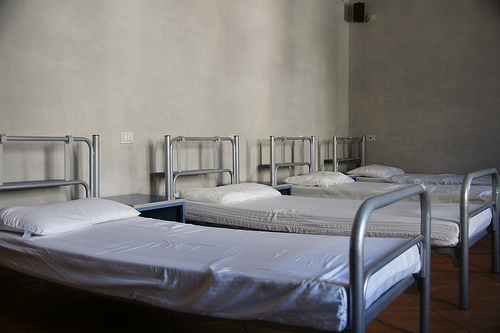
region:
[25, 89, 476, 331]
a row of beds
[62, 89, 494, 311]
beds in a row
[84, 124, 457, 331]
beds without blankets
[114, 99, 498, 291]
mattress covered in plastic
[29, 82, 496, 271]
tables in between beds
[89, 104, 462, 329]
a row of beds and table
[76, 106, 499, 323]
beds against the wall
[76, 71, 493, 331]
a row of beds inside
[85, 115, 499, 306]
beds that are inside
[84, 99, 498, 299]
beds with plastic mattress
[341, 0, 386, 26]
A piece of equipment attached to the wall.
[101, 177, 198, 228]
A table between the beds.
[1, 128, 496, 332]
Four gray iron beds.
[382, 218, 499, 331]
Brown concrete flooring.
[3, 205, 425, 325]
Four unmade beds with white coverlets.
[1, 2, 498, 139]
Gray concrete walls.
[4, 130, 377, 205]
The beds made shadows on the wall.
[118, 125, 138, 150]
The bed numbers are on the wall.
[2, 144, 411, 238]
A pillow is on each bed.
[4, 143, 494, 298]
The beds are empty.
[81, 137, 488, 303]
Four beds in the room.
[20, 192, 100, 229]
A pillow on the bed.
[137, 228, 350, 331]
The sheets are white.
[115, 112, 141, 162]
A light switch on the wall.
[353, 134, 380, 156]
An outlet on the wall.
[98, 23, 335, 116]
The wall is white.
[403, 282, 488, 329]
The floor is brown.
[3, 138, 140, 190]
The headboard is iron.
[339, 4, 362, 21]
A speaker in the corner.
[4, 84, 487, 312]
Four unoccupied beds with no sheets.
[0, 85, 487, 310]
Four unoccupied beds with no sheets in a room.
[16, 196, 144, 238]
pillow on a bed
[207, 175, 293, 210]
pillow on a bed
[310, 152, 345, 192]
pillow on a bed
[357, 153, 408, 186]
pillow on a bed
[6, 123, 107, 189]
head board of a bed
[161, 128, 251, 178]
head board on a bed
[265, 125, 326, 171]
head board on a bed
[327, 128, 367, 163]
head board on a bed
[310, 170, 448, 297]
bed in a room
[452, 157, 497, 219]
bed in a room